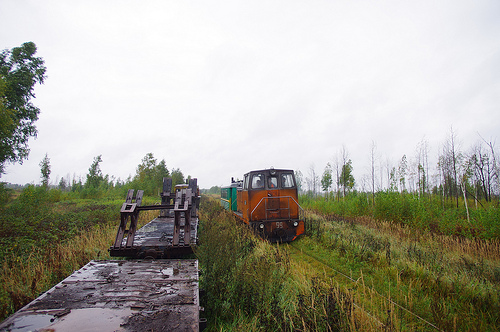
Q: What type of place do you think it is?
A: It is a field.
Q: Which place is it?
A: It is a field.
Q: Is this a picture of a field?
A: Yes, it is showing a field.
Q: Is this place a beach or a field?
A: It is a field.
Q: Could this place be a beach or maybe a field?
A: It is a field.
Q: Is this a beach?
A: No, it is a field.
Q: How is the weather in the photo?
A: It is cloudy.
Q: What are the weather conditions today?
A: It is cloudy.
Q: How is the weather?
A: It is cloudy.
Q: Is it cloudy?
A: Yes, it is cloudy.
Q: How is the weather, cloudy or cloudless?
A: It is cloudy.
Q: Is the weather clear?
A: No, it is cloudy.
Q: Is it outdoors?
A: Yes, it is outdoors.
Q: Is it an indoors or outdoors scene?
A: It is outdoors.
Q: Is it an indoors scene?
A: No, it is outdoors.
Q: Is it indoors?
A: No, it is outdoors.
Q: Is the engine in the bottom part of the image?
A: Yes, the engine is in the bottom of the image.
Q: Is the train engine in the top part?
A: No, the train engine is in the bottom of the image.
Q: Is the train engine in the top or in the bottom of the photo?
A: The train engine is in the bottom of the image.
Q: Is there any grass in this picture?
A: Yes, there is grass.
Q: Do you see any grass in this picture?
A: Yes, there is grass.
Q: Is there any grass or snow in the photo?
A: Yes, there is grass.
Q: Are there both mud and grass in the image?
A: No, there is grass but no mud.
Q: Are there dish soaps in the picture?
A: No, there are no dish soaps.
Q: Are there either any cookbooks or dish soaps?
A: No, there are no dish soaps or cookbooks.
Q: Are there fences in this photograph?
A: No, there are no fences.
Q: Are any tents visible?
A: No, there are no tents.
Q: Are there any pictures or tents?
A: No, there are no tents or pictures.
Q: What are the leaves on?
A: The leaves are on the tree.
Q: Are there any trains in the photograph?
A: Yes, there is a train.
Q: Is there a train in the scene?
A: Yes, there is a train.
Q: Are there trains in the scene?
A: Yes, there is a train.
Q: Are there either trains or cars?
A: Yes, there is a train.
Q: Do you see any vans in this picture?
A: No, there are no vans.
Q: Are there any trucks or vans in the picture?
A: No, there are no vans or trucks.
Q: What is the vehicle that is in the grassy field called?
A: The vehicle is a train.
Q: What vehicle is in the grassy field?
A: The vehicle is a train.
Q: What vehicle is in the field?
A: The vehicle is a train.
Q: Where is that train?
A: The train is in the field.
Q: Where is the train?
A: The train is in the field.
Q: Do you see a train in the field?
A: Yes, there is a train in the field.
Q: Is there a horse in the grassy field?
A: No, there is a train in the field.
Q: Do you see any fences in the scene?
A: No, there are no fences.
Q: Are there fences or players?
A: No, there are no fences or players.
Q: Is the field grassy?
A: Yes, the field is grassy.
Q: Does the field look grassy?
A: Yes, the field is grassy.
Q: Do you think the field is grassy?
A: Yes, the field is grassy.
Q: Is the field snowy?
A: No, the field is grassy.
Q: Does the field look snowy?
A: No, the field is grassy.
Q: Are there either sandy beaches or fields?
A: No, there is a field but it is grassy.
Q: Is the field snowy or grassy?
A: The field is grassy.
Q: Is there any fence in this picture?
A: No, there are no fences.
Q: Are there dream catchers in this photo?
A: No, there are no dream catchers.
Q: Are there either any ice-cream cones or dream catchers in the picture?
A: No, there are no dream catchers or ice-cream cones.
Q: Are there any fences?
A: No, there are no fences.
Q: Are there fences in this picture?
A: No, there are no fences.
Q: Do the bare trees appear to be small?
A: Yes, the trees are small.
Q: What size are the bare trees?
A: The trees are small.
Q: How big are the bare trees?
A: The trees are small.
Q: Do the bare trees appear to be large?
A: No, the trees are small.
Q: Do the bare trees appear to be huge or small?
A: The trees are small.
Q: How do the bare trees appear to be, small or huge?
A: The trees are small.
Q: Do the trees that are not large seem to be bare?
A: Yes, the trees are bare.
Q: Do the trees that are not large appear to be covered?
A: No, the trees are bare.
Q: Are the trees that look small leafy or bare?
A: The trees are bare.